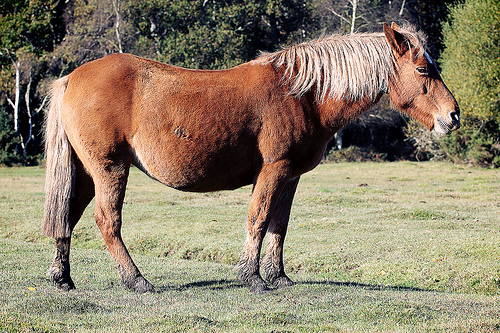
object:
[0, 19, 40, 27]
plant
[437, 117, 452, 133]
teeth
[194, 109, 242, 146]
coat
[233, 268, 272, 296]
horse hoof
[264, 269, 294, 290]
horse hoof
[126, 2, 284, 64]
shrub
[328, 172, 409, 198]
grass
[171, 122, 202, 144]
scar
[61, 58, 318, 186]
body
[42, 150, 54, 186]
edge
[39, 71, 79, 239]
tail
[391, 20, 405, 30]
ear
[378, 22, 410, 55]
ear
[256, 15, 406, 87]
mane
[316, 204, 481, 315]
grass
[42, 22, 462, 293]
horse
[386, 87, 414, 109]
jaw muscle